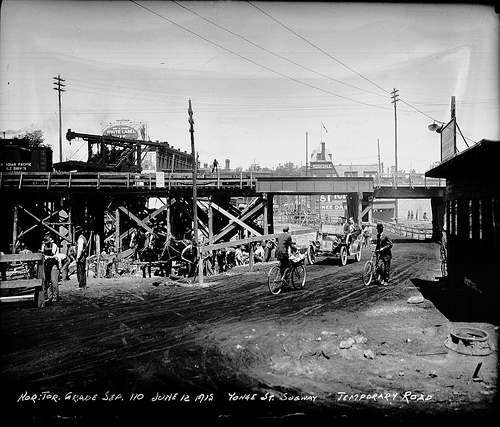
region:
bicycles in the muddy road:
[262, 215, 392, 295]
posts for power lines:
[390, 80, 400, 170]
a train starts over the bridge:
[0, 125, 51, 165]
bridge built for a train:
[0, 161, 440, 186]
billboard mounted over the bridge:
[435, 115, 455, 165]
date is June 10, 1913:
[150, 386, 215, 401]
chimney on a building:
[321, 140, 325, 159]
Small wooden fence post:
[14, 168, 24, 191]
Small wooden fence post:
[40, 167, 57, 190]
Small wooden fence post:
[64, 160, 76, 185]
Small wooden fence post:
[119, 167, 136, 192]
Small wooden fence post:
[140, 166, 160, 191]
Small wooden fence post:
[233, 164, 253, 191]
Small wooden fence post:
[389, 166, 404, 202]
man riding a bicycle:
[264, 222, 309, 294]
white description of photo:
[13, 387, 437, 407]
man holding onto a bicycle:
[362, 219, 394, 285]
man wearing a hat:
[38, 234, 61, 304]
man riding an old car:
[307, 215, 367, 264]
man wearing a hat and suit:
[369, 222, 395, 286]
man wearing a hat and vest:
[69, 224, 90, 288]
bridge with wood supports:
[9, 165, 446, 269]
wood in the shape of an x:
[116, 202, 166, 244]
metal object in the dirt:
[443, 323, 493, 358]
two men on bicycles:
[264, 219, 396, 301]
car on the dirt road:
[308, 209, 364, 268]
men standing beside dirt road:
[43, 222, 95, 297]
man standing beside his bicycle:
[358, 226, 392, 281]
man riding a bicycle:
[260, 231, 308, 295]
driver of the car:
[335, 217, 355, 237]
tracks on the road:
[43, 242, 413, 384]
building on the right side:
[435, 144, 498, 330]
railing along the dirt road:
[7, 226, 321, 304]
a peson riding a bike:
[270, 224, 304, 261]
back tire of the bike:
[265, 268, 287, 296]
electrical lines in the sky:
[341, 58, 376, 108]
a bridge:
[201, 167, 247, 188]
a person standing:
[72, 228, 93, 288]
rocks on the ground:
[335, 335, 378, 357]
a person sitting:
[346, 217, 359, 236]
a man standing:
[38, 233, 70, 305]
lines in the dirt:
[198, 285, 253, 316]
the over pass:
[3, 160, 445, 195]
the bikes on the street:
[181, 257, 386, 294]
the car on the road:
[303, 213, 366, 268]